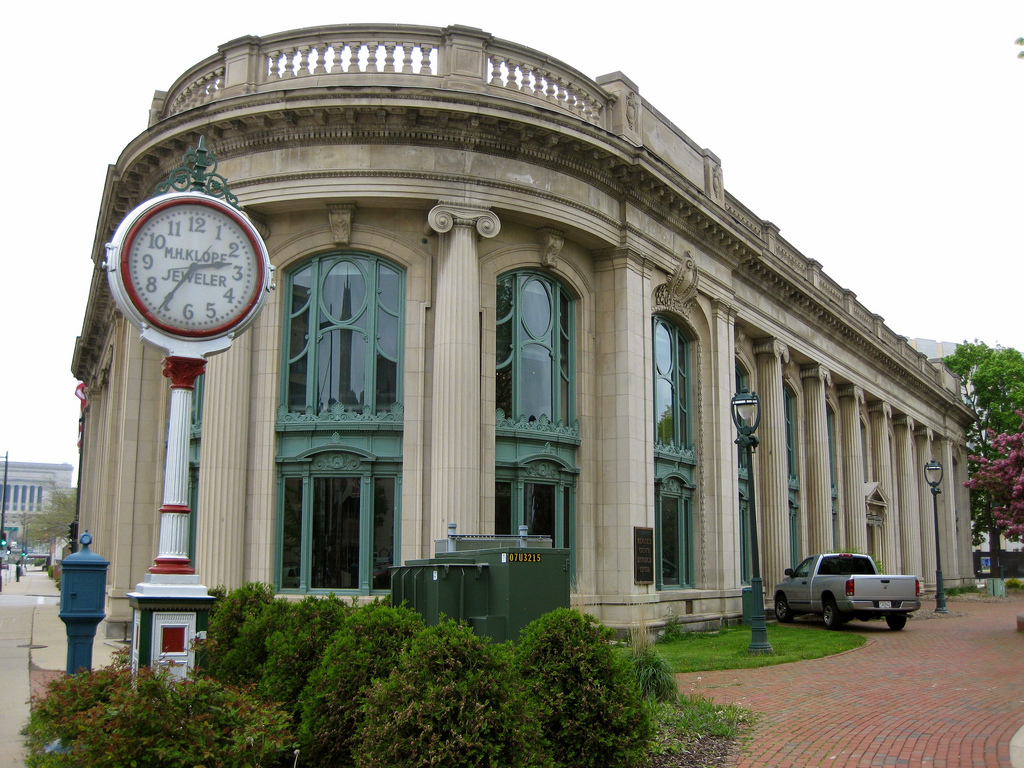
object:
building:
[128, 316, 769, 670]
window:
[492, 453, 561, 544]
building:
[68, 5, 985, 418]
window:
[652, 469, 704, 591]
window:
[733, 497, 769, 599]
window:
[786, 399, 810, 505]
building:
[570, 248, 971, 660]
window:
[788, 502, 808, 566]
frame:
[307, 282, 372, 397]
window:
[495, 261, 586, 447]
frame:
[517, 461, 564, 536]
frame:
[653, 311, 684, 448]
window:
[659, 315, 706, 469]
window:
[654, 438, 712, 626]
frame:
[656, 494, 696, 581]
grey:
[851, 561, 903, 592]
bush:
[381, 600, 623, 767]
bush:
[271, 595, 376, 723]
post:
[41, 499, 145, 768]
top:
[65, 536, 126, 616]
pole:
[735, 440, 777, 643]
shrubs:
[213, 577, 312, 687]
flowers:
[989, 445, 1000, 461]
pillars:
[30, 479, 40, 512]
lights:
[1, 536, 12, 551]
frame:
[555, 287, 579, 410]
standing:
[98, 173, 274, 657]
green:
[722, 369, 802, 650]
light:
[733, 367, 776, 534]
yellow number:
[510, 552, 516, 561]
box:
[358, 496, 607, 720]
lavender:
[1005, 512, 1021, 535]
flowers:
[1000, 465, 1022, 488]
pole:
[50, 615, 113, 735]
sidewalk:
[9, 564, 56, 768]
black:
[161, 259, 196, 309]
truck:
[770, 552, 921, 624]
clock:
[120, 193, 267, 336]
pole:
[128, 354, 219, 674]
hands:
[158, 262, 196, 307]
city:
[2, 4, 1021, 765]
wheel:
[818, 593, 845, 632]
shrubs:
[47, 631, 263, 764]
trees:
[980, 340, 1022, 578]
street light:
[917, 450, 952, 619]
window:
[282, 250, 406, 419]